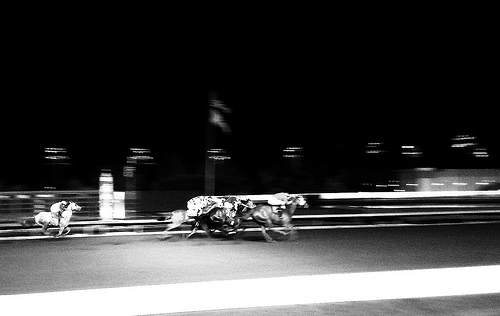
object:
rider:
[267, 192, 298, 214]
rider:
[186, 195, 226, 218]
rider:
[49, 201, 68, 219]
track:
[0, 215, 499, 314]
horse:
[241, 192, 310, 243]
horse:
[156, 197, 256, 241]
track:
[6, 202, 496, 308]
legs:
[55, 221, 66, 236]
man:
[215, 195, 236, 236]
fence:
[0, 259, 498, 315]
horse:
[19, 201, 82, 238]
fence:
[0, 189, 212, 226]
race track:
[0, 220, 499, 316]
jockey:
[248, 191, 309, 243]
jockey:
[161, 196, 256, 240]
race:
[0, 166, 497, 314]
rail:
[108, 266, 463, 303]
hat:
[62, 200, 70, 205]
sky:
[0, 0, 495, 193]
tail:
[18, 217, 35, 227]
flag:
[209, 109, 232, 132]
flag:
[210, 99, 233, 113]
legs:
[263, 219, 287, 235]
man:
[50, 201, 67, 219]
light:
[0, 264, 500, 316]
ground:
[0, 222, 499, 315]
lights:
[400, 145, 422, 157]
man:
[268, 192, 292, 221]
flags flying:
[209, 99, 233, 132]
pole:
[205, 89, 216, 194]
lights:
[44, 147, 70, 165]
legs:
[261, 225, 273, 243]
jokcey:
[50, 200, 70, 212]